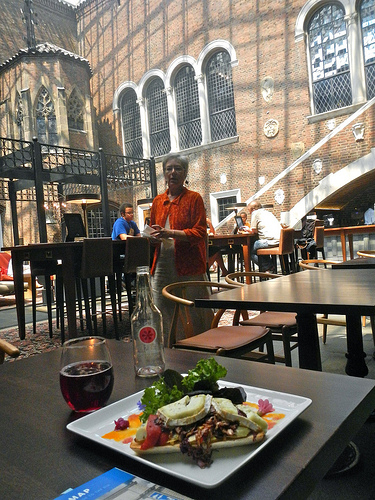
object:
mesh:
[210, 71, 230, 109]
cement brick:
[263, 119, 279, 139]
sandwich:
[129, 357, 269, 457]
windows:
[115, 41, 239, 173]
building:
[0, 1, 375, 259]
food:
[100, 356, 286, 469]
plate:
[67, 373, 313, 490]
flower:
[256, 399, 276, 418]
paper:
[52, 455, 189, 499]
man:
[238, 200, 282, 279]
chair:
[257, 228, 295, 275]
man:
[111, 203, 147, 293]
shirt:
[112, 217, 141, 240]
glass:
[59, 337, 115, 414]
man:
[116, 30, 238, 166]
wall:
[88, 1, 331, 200]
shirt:
[149, 185, 208, 276]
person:
[140, 151, 214, 349]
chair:
[161, 279, 275, 365]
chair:
[225, 270, 299, 367]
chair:
[78, 236, 117, 321]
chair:
[116, 236, 150, 323]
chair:
[299, 259, 347, 346]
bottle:
[130, 266, 166, 380]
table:
[196, 231, 375, 316]